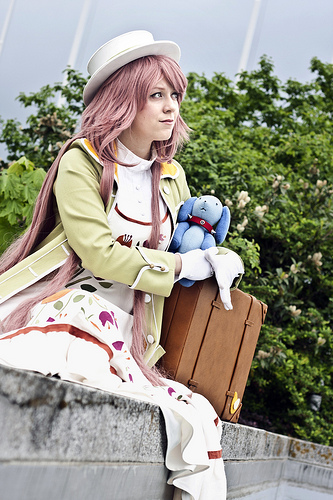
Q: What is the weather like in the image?
A: It is clear.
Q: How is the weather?
A: It is clear.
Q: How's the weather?
A: It is clear.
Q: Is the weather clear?
A: Yes, it is clear.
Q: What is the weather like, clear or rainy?
A: It is clear.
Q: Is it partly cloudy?
A: No, it is clear.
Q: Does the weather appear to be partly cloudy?
A: No, it is clear.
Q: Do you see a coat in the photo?
A: Yes, there is a coat.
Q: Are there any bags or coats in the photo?
A: Yes, there is a coat.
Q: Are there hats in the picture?
A: Yes, there is a hat.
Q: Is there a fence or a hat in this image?
A: Yes, there is a hat.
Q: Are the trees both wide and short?
A: Yes, the trees are wide and short.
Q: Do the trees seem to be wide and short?
A: Yes, the trees are wide and short.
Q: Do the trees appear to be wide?
A: Yes, the trees are wide.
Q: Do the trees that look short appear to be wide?
A: Yes, the trees are wide.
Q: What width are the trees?
A: The trees are wide.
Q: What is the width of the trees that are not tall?
A: The trees are wide.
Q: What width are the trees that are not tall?
A: The trees are wide.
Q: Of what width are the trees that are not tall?
A: The trees are wide.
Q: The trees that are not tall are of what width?
A: The trees are wide.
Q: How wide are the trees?
A: The trees are wide.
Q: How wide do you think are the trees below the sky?
A: The trees are wide.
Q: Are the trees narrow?
A: No, the trees are wide.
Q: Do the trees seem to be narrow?
A: No, the trees are wide.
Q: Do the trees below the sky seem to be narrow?
A: No, the trees are wide.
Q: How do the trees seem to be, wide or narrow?
A: The trees are wide.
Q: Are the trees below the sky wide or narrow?
A: The trees are wide.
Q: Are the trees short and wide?
A: Yes, the trees are short and wide.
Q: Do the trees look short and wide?
A: Yes, the trees are short and wide.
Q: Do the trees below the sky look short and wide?
A: Yes, the trees are short and wide.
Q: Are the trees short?
A: Yes, the trees are short.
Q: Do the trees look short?
A: Yes, the trees are short.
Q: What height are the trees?
A: The trees are short.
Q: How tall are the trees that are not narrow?
A: The trees are short.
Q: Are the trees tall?
A: No, the trees are short.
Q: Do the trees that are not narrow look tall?
A: No, the trees are short.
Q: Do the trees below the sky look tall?
A: No, the trees are short.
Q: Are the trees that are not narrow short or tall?
A: The trees are short.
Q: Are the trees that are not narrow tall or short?
A: The trees are short.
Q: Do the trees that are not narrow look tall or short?
A: The trees are short.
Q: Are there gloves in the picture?
A: Yes, there are gloves.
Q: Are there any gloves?
A: Yes, there are gloves.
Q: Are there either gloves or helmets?
A: Yes, there are gloves.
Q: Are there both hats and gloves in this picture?
A: Yes, there are both gloves and a hat.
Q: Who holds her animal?
A: The girl holds the animal.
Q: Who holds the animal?
A: The girl holds the animal.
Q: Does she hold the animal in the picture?
A: Yes, the girl holds the animal.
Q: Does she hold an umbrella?
A: No, the girl holds the animal.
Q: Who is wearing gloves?
A: The girl is wearing gloves.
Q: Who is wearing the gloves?
A: The girl is wearing gloves.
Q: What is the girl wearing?
A: The girl is wearing gloves.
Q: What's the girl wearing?
A: The girl is wearing gloves.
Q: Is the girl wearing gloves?
A: Yes, the girl is wearing gloves.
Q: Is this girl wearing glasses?
A: No, the girl is wearing gloves.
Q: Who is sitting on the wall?
A: The girl is sitting on the wall.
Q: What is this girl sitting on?
A: The girl is sitting on the wall.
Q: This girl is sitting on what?
A: The girl is sitting on the wall.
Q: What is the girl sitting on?
A: The girl is sitting on the wall.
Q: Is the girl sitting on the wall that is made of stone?
A: Yes, the girl is sitting on the wall.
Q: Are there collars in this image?
A: Yes, there is a collar.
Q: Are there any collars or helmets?
A: Yes, there is a collar.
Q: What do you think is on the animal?
A: The collar is on the animal.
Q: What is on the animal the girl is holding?
A: The collar is on the animal.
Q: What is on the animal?
A: The collar is on the animal.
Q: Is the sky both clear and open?
A: Yes, the sky is clear and open.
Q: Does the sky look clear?
A: Yes, the sky is clear.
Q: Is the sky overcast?
A: No, the sky is clear.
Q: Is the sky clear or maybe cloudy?
A: The sky is clear.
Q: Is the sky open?
A: Yes, the sky is open.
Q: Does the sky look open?
A: Yes, the sky is open.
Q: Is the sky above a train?
A: No, the sky is above the girl.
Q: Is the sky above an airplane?
A: No, the sky is above the animal.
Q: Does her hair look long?
A: Yes, the hair is long.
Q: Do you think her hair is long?
A: Yes, the hair is long.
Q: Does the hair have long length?
A: Yes, the hair is long.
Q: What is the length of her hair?
A: The hair is long.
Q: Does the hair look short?
A: No, the hair is long.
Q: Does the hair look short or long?
A: The hair is long.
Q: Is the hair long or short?
A: The hair is long.